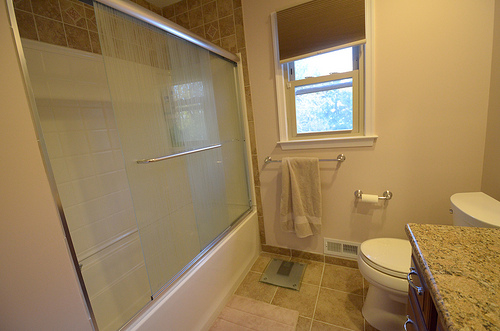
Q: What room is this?
A: Bathroom.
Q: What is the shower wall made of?
A: Tile.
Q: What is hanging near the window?
A: Towel.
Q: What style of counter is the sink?
A: Marble.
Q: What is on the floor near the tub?
A: Scale.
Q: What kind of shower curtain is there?
A: Glass doors.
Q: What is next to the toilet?
A: Toilet paper.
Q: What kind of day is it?
A: Sunny.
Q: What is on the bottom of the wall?
A: Vent.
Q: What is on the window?
A: Shades.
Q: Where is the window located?
A: The window is on the wall.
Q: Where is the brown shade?
A: On the window.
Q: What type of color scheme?
A: A neutral color scheme.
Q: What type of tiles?
A: White tiles in the area.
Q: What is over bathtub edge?
A: The glass doors are.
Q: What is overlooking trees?
A: The window is overlooking.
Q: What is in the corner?
A: White toilet seat.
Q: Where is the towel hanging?
A: On a towel rack.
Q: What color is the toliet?
A: White.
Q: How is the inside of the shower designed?
A: It is tiled.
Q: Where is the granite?
A: On top of the vanity.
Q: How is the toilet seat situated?
A: It is down.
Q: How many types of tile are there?
A: Three.